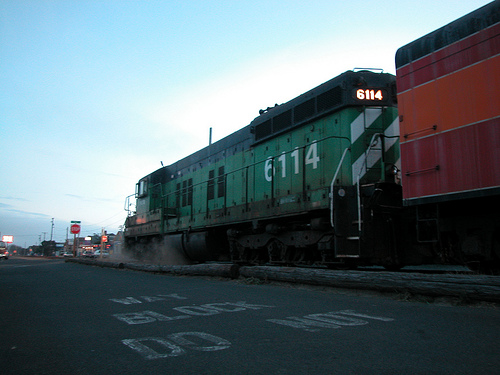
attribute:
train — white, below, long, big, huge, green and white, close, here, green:
[140, 67, 392, 213]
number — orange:
[346, 80, 390, 110]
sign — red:
[68, 213, 88, 244]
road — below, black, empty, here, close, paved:
[41, 256, 207, 371]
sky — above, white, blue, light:
[134, 5, 217, 54]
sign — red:
[69, 220, 80, 230]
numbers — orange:
[355, 85, 384, 103]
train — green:
[121, 66, 401, 264]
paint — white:
[110, 283, 393, 360]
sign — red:
[67, 219, 82, 237]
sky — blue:
[3, 0, 498, 245]